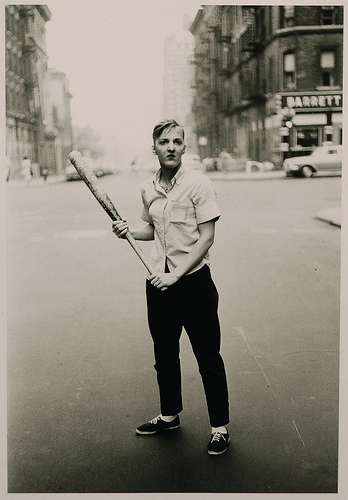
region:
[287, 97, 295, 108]
white letter on sign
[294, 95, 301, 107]
white letter on sign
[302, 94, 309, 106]
white letter on sign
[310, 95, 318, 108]
white letter on sign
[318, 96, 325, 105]
white letter on sign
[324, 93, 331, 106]
white letter on sign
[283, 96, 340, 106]
white letters on sign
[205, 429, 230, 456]
black colored tennis shoe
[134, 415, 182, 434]
black colored tennis shoe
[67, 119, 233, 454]
a person holding a baseball bat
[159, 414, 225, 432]
a couple of white socks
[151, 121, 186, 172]
the head of the person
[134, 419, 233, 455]
a couple of sneakers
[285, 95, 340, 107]
the word BARRETT out of focus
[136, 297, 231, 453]
the two legs of the person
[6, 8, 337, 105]
old buildings in the background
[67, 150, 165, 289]
a baseball bat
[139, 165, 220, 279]
the person is wearing a short sleeve shirt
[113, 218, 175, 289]
the two hands of the person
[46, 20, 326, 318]
The photo is in black and white.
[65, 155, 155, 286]
A person holding a bat.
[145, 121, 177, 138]
The woman has short hair.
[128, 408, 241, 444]
White shoe laces on the shoes.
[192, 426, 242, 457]
The sneakers are black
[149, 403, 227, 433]
The lady is wearing white socks.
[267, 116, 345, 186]
A car on the street.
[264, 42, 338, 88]
The windows is open on the building.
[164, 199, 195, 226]
A pocket on the shirt.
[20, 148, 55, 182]
People walking on the sidewalk.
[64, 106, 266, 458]
person holding a bat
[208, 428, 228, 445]
white shoelaces on the shoe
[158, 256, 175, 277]
bottom of the shirt is open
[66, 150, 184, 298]
two hands on the bat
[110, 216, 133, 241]
fingers wrapped around the bat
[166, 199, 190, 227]
pocket on the shirt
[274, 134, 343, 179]
car on the side of the road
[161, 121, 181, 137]
hair laying over the forehead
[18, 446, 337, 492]
shadow on the ground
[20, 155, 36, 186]
person on the sidewalk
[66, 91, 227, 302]
Person holding a baseball bat.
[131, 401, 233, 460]
Person wearing dark sneakers.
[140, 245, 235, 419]
Person wearing dark pants.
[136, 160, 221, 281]
Person wearing a light colored shirt.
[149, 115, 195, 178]
Person with a scowl on their face.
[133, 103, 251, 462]
Person standing in the street.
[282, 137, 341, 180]
Car parked at the curb.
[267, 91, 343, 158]
A store across the street.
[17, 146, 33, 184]
Woman walking on the sidewalk.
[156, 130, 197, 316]
child standing on the street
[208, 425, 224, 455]
dark shoes in the left foot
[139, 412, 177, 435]
dark shoes in the right foot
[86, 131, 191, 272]
kid whit a baseball bat in his hands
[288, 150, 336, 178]
old car standing on the pavement